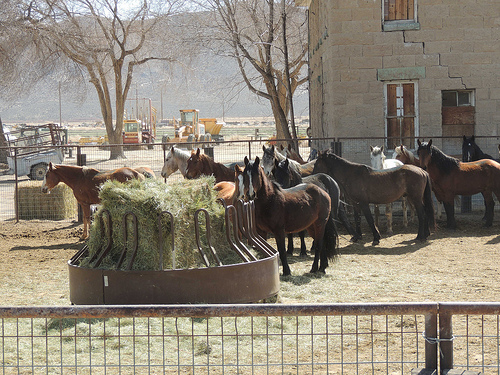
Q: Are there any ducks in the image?
A: No, there are no ducks.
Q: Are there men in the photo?
A: No, there are no men.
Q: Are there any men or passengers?
A: No, there are no men or passengers.